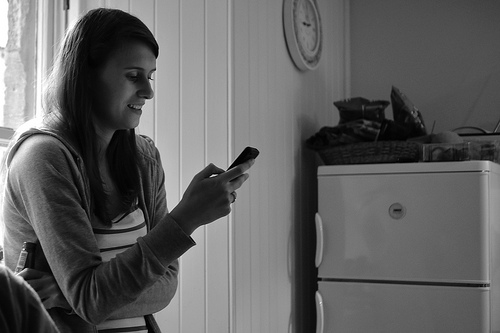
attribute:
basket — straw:
[313, 139, 420, 166]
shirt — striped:
[88, 210, 176, 290]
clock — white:
[278, 0, 325, 73]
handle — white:
[312, 213, 322, 265]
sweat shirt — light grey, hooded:
[0, 125, 197, 321]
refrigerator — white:
[313, 135, 498, 325]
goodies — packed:
[339, 104, 404, 169]